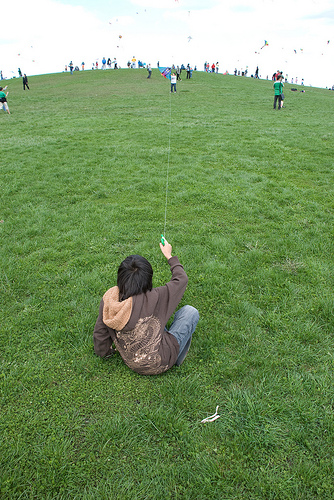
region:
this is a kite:
[164, 67, 174, 79]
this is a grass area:
[218, 371, 314, 495]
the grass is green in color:
[223, 327, 289, 419]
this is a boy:
[84, 239, 189, 365]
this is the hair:
[131, 264, 141, 282]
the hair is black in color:
[130, 277, 147, 291]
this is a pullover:
[151, 295, 180, 323]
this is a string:
[164, 130, 179, 201]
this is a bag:
[280, 91, 285, 99]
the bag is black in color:
[279, 91, 286, 99]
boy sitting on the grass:
[102, 320, 201, 398]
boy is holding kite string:
[120, 184, 202, 279]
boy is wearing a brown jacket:
[86, 290, 142, 354]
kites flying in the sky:
[262, 35, 313, 60]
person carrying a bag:
[278, 81, 286, 107]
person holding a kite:
[154, 68, 180, 83]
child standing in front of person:
[278, 89, 292, 108]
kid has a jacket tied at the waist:
[1, 95, 15, 121]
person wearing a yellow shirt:
[128, 57, 139, 63]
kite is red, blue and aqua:
[158, 62, 181, 81]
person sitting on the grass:
[84, 226, 214, 382]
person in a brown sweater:
[83, 236, 214, 379]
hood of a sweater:
[95, 277, 146, 332]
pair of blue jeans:
[161, 301, 204, 364]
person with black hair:
[78, 230, 210, 386]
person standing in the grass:
[165, 68, 180, 94]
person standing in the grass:
[271, 76, 286, 109]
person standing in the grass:
[20, 72, 30, 92]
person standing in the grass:
[181, 65, 191, 78]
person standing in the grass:
[100, 55, 107, 68]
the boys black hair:
[113, 248, 145, 281]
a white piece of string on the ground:
[201, 402, 223, 426]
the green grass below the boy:
[19, 402, 84, 466]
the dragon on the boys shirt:
[118, 331, 158, 373]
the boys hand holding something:
[159, 240, 175, 259]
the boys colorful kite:
[156, 64, 172, 81]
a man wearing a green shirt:
[267, 74, 295, 110]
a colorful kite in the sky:
[255, 35, 271, 55]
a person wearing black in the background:
[19, 73, 46, 102]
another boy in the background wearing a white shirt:
[165, 72, 187, 92]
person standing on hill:
[166, 73, 175, 95]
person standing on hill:
[271, 72, 290, 117]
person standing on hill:
[216, 58, 222, 79]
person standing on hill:
[18, 67, 35, 93]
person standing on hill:
[0, 96, 18, 119]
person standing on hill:
[64, 57, 77, 77]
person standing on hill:
[100, 55, 104, 67]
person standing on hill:
[112, 55, 117, 72]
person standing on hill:
[250, 65, 267, 82]